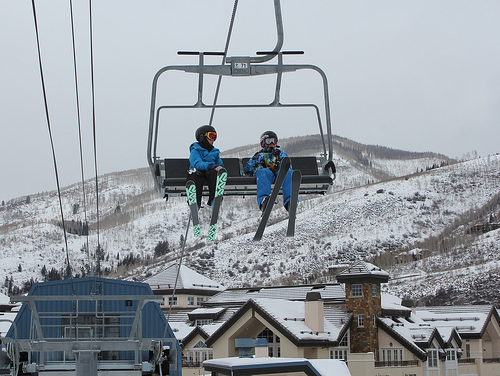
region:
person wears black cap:
[185, 120, 215, 157]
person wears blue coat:
[183, 138, 229, 188]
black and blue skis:
[171, 172, 223, 261]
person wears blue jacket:
[257, 147, 285, 175]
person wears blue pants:
[253, 163, 305, 213]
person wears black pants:
[182, 163, 230, 195]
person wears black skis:
[255, 165, 307, 237]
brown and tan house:
[242, 292, 482, 360]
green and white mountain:
[327, 115, 476, 232]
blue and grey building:
[23, 265, 174, 374]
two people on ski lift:
[157, 48, 361, 245]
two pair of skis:
[184, 151, 314, 247]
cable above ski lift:
[200, 45, 240, 116]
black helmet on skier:
[187, 120, 217, 145]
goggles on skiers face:
[262, 133, 282, 145]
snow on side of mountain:
[369, 165, 462, 221]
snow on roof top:
[251, 294, 308, 337]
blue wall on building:
[36, 278, 150, 343]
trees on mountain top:
[351, 135, 414, 160]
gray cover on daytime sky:
[370, 57, 455, 122]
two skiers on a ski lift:
[132, 42, 375, 251]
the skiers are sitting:
[172, 127, 302, 229]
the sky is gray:
[353, 7, 476, 123]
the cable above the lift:
[221, 3, 239, 43]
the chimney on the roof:
[302, 283, 339, 331]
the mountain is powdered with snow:
[369, 180, 492, 282]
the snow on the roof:
[262, 293, 297, 323]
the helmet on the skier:
[252, 125, 292, 145]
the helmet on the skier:
[186, 120, 221, 139]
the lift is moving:
[138, 38, 364, 211]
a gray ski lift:
[138, 27, 373, 243]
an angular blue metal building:
[11, 274, 171, 371]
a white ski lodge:
[193, 277, 343, 372]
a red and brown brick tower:
[346, 276, 381, 363]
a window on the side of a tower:
[351, 278, 366, 300]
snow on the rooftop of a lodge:
[268, 295, 292, 320]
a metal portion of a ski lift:
[3, 279, 160, 360]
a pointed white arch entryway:
[217, 305, 287, 358]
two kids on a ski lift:
[168, 115, 306, 232]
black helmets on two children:
[193, 123, 290, 155]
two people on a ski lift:
[133, 53, 347, 245]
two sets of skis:
[166, 157, 319, 244]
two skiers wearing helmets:
[161, 124, 310, 244]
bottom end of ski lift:
[0, 266, 182, 375]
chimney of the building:
[337, 266, 392, 369]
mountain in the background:
[1, 122, 497, 281]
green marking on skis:
[170, 148, 245, 240]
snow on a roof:
[256, 285, 337, 344]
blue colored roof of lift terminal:
[12, 267, 187, 334]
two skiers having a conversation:
[161, 124, 303, 228]